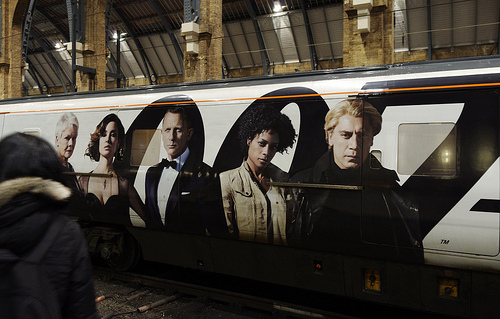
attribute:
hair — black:
[237, 100, 296, 153]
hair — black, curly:
[238, 110, 302, 147]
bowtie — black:
[159, 157, 178, 169]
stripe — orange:
[0, 82, 499, 114]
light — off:
[167, 16, 206, 56]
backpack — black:
[10, 232, 65, 317]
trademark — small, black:
[435, 235, 452, 247]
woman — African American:
[217, 105, 312, 240]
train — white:
[2, 56, 496, 314]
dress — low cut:
[74, 170, 127, 241]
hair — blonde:
[319, 91, 384, 134]